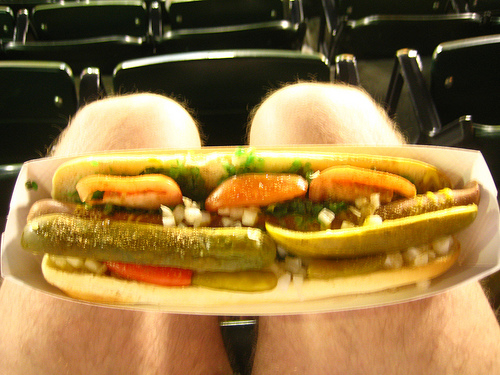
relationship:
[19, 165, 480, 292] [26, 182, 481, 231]
toppings on hotdog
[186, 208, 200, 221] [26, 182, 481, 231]
onion on hotdog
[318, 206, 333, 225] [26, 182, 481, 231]
onion on hotdog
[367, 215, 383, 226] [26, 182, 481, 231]
onion on hotdog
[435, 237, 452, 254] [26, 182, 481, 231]
onion on hotdog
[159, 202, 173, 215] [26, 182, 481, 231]
onion on hotdog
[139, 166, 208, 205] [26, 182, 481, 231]
relish on hotdog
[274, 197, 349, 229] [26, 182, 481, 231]
relish on hotdog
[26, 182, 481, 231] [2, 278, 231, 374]
hotdog on leg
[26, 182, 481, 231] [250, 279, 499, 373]
hotdog on leg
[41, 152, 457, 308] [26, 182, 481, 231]
hotdog bun under hotdog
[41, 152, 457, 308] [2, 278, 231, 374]
food on leg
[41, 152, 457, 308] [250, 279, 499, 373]
food on leg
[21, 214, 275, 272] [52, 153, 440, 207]
pickle on hotdog bun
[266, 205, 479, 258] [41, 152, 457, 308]
pickle on hotdog bun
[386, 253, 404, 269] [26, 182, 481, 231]
onion on hotdog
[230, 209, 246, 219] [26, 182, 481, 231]
onion on hotdog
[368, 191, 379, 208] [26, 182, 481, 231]
onion on hotdog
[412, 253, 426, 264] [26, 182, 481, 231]
onion on hotdog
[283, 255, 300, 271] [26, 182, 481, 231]
onion on hotdog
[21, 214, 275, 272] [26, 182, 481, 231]
pickle on hotdog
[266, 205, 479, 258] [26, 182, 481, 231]
pickle on hotdog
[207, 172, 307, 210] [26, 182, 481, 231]
tomato on hotdog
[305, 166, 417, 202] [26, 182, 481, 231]
tomato on hotdog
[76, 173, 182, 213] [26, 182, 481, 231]
tomato on hotdog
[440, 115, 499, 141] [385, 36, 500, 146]
top of chair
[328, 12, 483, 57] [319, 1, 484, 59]
top of chair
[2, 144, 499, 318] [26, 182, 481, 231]
box holding hotdog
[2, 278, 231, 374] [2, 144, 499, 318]
leg under box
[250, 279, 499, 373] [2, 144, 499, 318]
leg under box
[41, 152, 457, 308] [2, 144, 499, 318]
hotdog bun in box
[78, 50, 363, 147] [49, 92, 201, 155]
chair in front of knee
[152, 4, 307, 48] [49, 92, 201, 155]
chair in front of knee